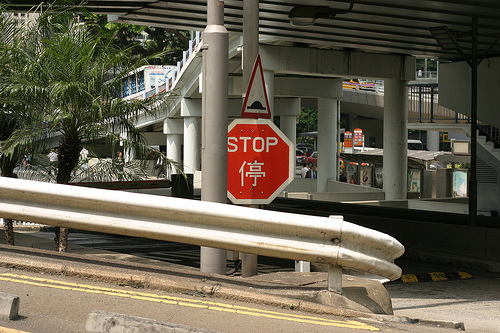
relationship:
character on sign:
[237, 159, 265, 189] [228, 119, 296, 206]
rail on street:
[1, 172, 405, 295] [5, 222, 497, 330]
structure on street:
[342, 147, 443, 197] [5, 222, 497, 330]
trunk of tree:
[56, 226, 70, 253] [2, 4, 172, 249]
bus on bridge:
[99, 63, 174, 101] [0, 38, 204, 167]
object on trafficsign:
[246, 100, 267, 110] [239, 52, 272, 118]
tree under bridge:
[2, 4, 172, 249] [0, 38, 204, 167]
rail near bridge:
[1, 172, 405, 295] [0, 38, 204, 167]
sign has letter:
[228, 119, 296, 206] [227, 134, 278, 154]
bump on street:
[394, 267, 474, 285] [5, 222, 497, 330]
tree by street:
[2, 4, 172, 249] [5, 222, 497, 330]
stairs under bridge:
[467, 125, 499, 162] [0, 38, 204, 167]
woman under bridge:
[299, 162, 309, 179] [0, 38, 204, 167]